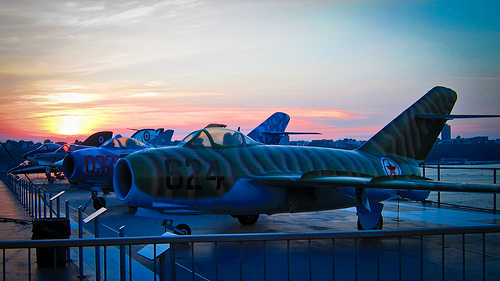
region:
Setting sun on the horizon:
[24, 95, 107, 133]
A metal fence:
[127, 226, 294, 279]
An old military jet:
[112, 116, 415, 207]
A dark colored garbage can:
[24, 208, 81, 272]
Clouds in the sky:
[0, 2, 241, 85]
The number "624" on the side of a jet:
[155, 122, 248, 203]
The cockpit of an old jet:
[175, 119, 264, 147]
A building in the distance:
[436, 123, 462, 143]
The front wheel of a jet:
[164, 215, 193, 241]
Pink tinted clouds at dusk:
[115, 94, 256, 123]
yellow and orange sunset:
[22, 75, 224, 130]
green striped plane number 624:
[131, 137, 431, 210]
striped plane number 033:
[67, 132, 116, 193]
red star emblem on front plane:
[371, 147, 414, 188]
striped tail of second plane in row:
[250, 108, 303, 140]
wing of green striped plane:
[262, 152, 499, 212]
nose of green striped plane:
[110, 155, 165, 216]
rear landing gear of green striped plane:
[344, 197, 406, 267]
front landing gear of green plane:
[142, 212, 215, 246]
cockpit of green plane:
[188, 112, 274, 157]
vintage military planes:
[11, 56, 494, 265]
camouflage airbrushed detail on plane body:
[143, 149, 499, 208]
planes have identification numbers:
[56, 119, 238, 236]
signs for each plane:
[21, 176, 182, 258]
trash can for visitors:
[12, 200, 84, 280]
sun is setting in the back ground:
[15, 39, 335, 185]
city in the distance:
[433, 100, 493, 182]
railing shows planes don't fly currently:
[7, 111, 486, 262]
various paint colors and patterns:
[28, 132, 171, 248]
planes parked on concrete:
[201, 167, 494, 274]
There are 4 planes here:
[21, 126, 445, 246]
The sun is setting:
[32, 75, 252, 187]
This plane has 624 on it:
[143, 151, 274, 213]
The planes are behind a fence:
[19, 171, 186, 280]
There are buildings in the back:
[318, 106, 494, 177]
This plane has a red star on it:
[105, 141, 426, 205]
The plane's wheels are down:
[222, 197, 408, 240]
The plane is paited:
[153, 159, 390, 220]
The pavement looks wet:
[199, 221, 404, 278]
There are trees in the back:
[5, 129, 168, 211]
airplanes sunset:
[85, 125, 475, 228]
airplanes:
[66, 97, 421, 270]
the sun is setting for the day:
[36, 25, 351, 146]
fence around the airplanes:
[36, 192, 99, 272]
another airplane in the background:
[42, 111, 120, 187]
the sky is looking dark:
[180, 22, 472, 107]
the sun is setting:
[41, 71, 122, 136]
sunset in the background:
[27, 87, 118, 157]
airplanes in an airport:
[32, 80, 407, 280]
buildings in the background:
[431, 122, 493, 168]